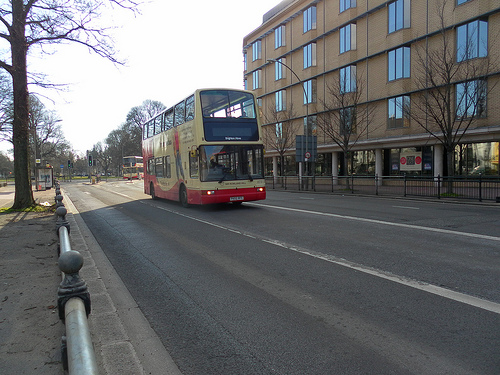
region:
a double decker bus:
[133, 91, 268, 205]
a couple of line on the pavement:
[306, 202, 491, 317]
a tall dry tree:
[401, 30, 489, 200]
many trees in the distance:
[30, 104, 141, 170]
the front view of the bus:
[198, 91, 262, 203]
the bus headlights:
[200, 187, 265, 197]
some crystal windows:
[269, 26, 419, 126]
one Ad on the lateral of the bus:
[167, 126, 197, 184]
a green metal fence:
[330, 172, 498, 202]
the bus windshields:
[198, 144, 261, 183]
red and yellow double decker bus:
[139, 87, 269, 209]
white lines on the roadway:
[95, 178, 492, 320]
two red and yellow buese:
[120, 85, 269, 206]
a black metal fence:
[262, 170, 498, 202]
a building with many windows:
[243, 0, 498, 185]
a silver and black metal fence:
[47, 174, 102, 374]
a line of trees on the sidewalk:
[257, 0, 489, 197]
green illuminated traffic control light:
[63, 151, 94, 171]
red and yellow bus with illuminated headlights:
[140, 87, 263, 203]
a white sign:
[31, 165, 55, 189]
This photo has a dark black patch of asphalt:
[259, 264, 288, 326]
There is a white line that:
[348, 253, 363, 298]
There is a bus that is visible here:
[179, 114, 219, 188]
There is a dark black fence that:
[415, 15, 422, 174]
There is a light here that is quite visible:
[204, 186, 214, 206]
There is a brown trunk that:
[9, 168, 41, 230]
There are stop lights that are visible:
[68, 154, 83, 199]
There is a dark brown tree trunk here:
[78, 0, 98, 42]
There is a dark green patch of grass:
[16, 198, 26, 214]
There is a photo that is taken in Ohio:
[176, 55, 268, 270]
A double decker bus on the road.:
[143, 87, 269, 208]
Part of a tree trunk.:
[13, 119, 33, 211]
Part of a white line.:
[361, 256, 413, 287]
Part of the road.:
[237, 303, 287, 348]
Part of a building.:
[364, 30, 379, 47]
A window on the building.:
[386, 46, 409, 81]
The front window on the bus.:
[201, 142, 266, 180]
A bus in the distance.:
[121, 155, 144, 180]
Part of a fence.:
[468, 178, 498, 200]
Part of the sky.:
[71, 86, 108, 110]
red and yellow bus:
[122, 92, 267, 238]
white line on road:
[269, 235, 499, 352]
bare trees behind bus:
[244, 74, 490, 204]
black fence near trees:
[344, 151, 481, 201]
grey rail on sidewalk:
[47, 203, 95, 370]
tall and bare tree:
[4, 1, 79, 215]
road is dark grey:
[152, 60, 491, 373]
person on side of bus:
[162, 122, 201, 191]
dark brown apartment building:
[242, 11, 484, 181]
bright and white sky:
[131, 11, 223, 88]